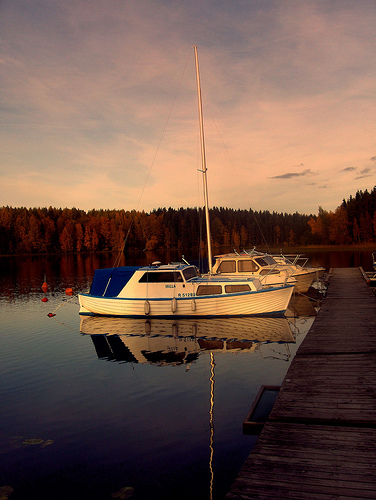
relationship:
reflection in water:
[80, 315, 297, 367] [2, 245, 331, 499]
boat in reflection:
[77, 259, 295, 318] [80, 315, 297, 367]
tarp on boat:
[88, 265, 147, 299] [77, 259, 295, 318]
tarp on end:
[88, 265, 147, 299] [74, 261, 141, 325]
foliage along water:
[2, 206, 374, 246] [2, 245, 331, 499]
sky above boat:
[1, 1, 375, 215] [77, 259, 295, 318]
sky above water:
[1, 1, 375, 215] [2, 245, 331, 499]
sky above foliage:
[1, 1, 375, 215] [2, 206, 374, 246]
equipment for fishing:
[258, 263, 293, 284] [111, 475, 147, 498]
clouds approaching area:
[266, 150, 375, 193] [3, 3, 373, 493]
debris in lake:
[233, 379, 282, 434] [2, 245, 331, 499]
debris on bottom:
[233, 379, 282, 434] [215, 382, 321, 447]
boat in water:
[77, 259, 295, 318] [2, 245, 331, 499]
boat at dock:
[77, 259, 295, 318] [225, 267, 375, 498]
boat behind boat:
[77, 259, 295, 318] [77, 259, 295, 318]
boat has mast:
[77, 259, 295, 318] [192, 41, 214, 277]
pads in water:
[10, 433, 55, 453] [2, 245, 331, 499]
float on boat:
[187, 299, 199, 313] [77, 259, 295, 318]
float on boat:
[169, 296, 181, 315] [77, 259, 295, 318]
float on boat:
[141, 298, 151, 316] [77, 259, 295, 318]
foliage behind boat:
[2, 206, 374, 246] [77, 259, 295, 318]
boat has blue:
[77, 259, 295, 318] [78, 290, 295, 301]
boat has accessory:
[77, 259, 295, 318] [151, 260, 182, 269]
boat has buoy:
[77, 259, 295, 318] [45, 310, 55, 318]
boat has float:
[77, 259, 295, 318] [187, 299, 199, 313]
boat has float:
[77, 259, 295, 318] [169, 296, 181, 315]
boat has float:
[77, 259, 295, 318] [141, 298, 151, 316]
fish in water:
[124, 417, 155, 432] [2, 245, 331, 499]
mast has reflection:
[192, 41, 214, 277] [200, 334, 222, 499]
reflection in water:
[200, 334, 222, 499] [2, 245, 331, 499]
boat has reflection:
[77, 259, 295, 318] [80, 315, 297, 367]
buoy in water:
[41, 278, 50, 292] [2, 245, 331, 499]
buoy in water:
[64, 285, 72, 295] [2, 245, 331, 499]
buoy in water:
[38, 295, 51, 304] [2, 245, 331, 499]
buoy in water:
[47, 309, 54, 323] [2, 245, 331, 499]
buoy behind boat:
[41, 278, 50, 292] [77, 259, 295, 318]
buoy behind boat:
[64, 285, 72, 295] [77, 259, 295, 318]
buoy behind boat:
[38, 295, 51, 304] [77, 259, 295, 318]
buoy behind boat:
[45, 310, 55, 318] [77, 259, 295, 318]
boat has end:
[77, 259, 295, 318] [74, 261, 141, 325]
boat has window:
[77, 259, 295, 318] [140, 270, 183, 284]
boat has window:
[77, 259, 295, 318] [183, 267, 202, 280]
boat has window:
[77, 259, 295, 318] [196, 283, 223, 295]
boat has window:
[77, 259, 295, 318] [224, 284, 251, 293]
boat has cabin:
[77, 259, 295, 318] [136, 262, 259, 293]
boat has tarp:
[77, 259, 295, 318] [88, 265, 147, 299]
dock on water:
[225, 267, 375, 498] [2, 245, 331, 499]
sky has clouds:
[1, 1, 375, 215] [266, 150, 375, 193]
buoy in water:
[47, 311, 53, 318] [2, 245, 331, 499]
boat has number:
[77, 259, 295, 318] [177, 292, 196, 297]